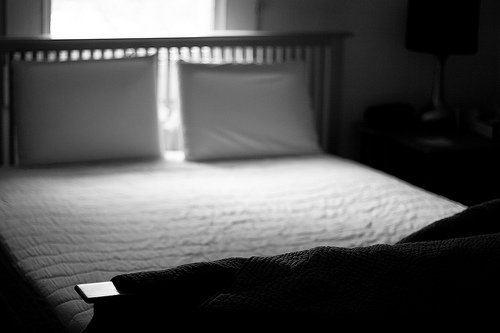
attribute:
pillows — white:
[9, 57, 321, 157]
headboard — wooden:
[0, 28, 352, 165]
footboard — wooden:
[87, 260, 119, 308]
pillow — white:
[175, 56, 322, 164]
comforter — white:
[3, 162, 440, 242]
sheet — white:
[3, 156, 468, 323]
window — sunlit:
[45, 1, 227, 48]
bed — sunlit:
[2, 27, 484, 328]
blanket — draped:
[76, 196, 498, 318]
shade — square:
[399, 1, 480, 55]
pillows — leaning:
[13, 61, 323, 171]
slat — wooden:
[0, 20, 355, 49]